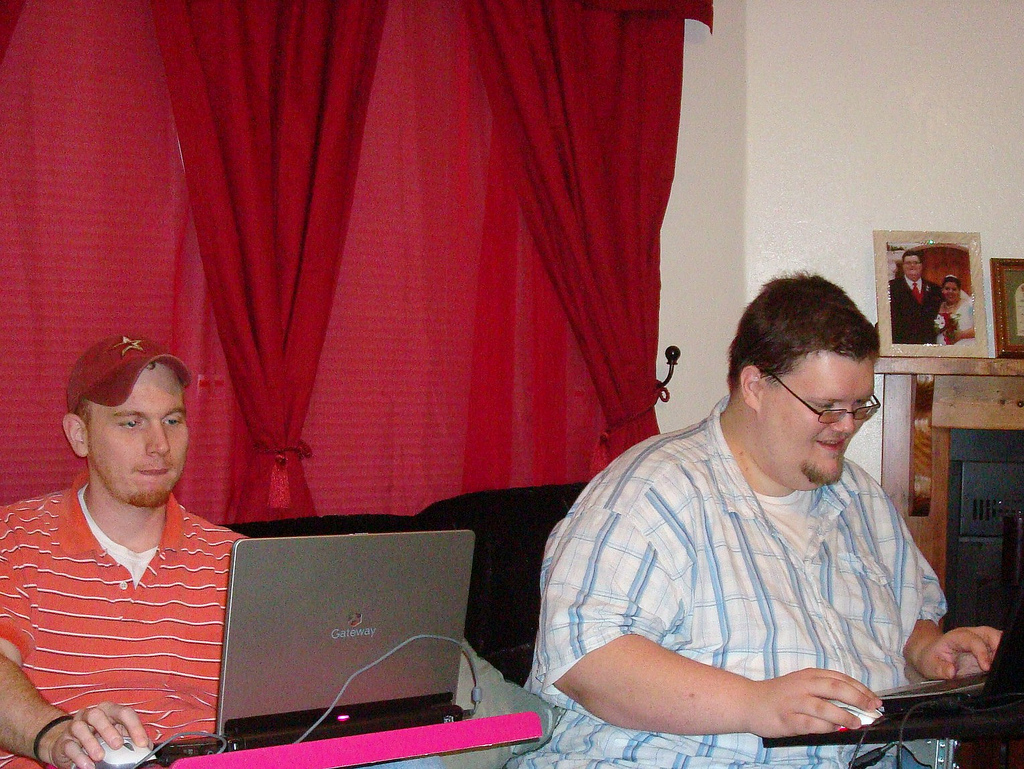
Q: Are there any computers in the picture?
A: Yes, there is a computer.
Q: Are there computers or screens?
A: Yes, there is a computer.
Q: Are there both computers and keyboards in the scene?
A: Yes, there are both a computer and a keyboard.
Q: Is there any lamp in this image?
A: No, there are no lamps.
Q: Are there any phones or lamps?
A: No, there are no lamps or phones.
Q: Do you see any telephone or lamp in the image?
A: No, there are no lamps or phones.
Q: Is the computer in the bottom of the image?
A: Yes, the computer is in the bottom of the image.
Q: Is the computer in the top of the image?
A: No, the computer is in the bottom of the image.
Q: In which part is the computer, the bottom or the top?
A: The computer is in the bottom of the image.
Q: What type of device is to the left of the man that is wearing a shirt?
A: The device is a computer.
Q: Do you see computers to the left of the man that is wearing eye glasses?
A: Yes, there is a computer to the left of the man.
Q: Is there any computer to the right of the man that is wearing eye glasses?
A: No, the computer is to the left of the man.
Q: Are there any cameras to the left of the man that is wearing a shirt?
A: No, there is a computer to the left of the man.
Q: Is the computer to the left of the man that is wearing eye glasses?
A: Yes, the computer is to the left of the man.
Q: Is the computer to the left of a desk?
A: No, the computer is to the left of the man.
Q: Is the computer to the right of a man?
A: No, the computer is to the left of a man.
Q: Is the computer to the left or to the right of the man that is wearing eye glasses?
A: The computer is to the left of the man.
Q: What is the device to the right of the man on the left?
A: The device is a computer.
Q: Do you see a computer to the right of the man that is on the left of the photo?
A: Yes, there is a computer to the right of the man.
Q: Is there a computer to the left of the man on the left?
A: No, the computer is to the right of the man.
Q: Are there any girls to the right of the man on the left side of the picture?
A: No, there is a computer to the right of the man.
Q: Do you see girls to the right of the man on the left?
A: No, there is a computer to the right of the man.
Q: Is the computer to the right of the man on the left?
A: Yes, the computer is to the right of the man.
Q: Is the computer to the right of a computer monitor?
A: No, the computer is to the right of the man.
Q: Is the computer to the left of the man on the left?
A: No, the computer is to the right of the man.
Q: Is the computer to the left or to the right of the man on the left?
A: The computer is to the right of the man.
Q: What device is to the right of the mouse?
A: The device is a computer.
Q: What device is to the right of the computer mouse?
A: The device is a computer.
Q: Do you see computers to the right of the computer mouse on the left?
A: Yes, there is a computer to the right of the computer mouse.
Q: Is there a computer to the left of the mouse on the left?
A: No, the computer is to the right of the computer mouse.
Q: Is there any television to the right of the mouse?
A: No, there is a computer to the right of the mouse.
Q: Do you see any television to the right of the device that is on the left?
A: No, there is a computer to the right of the mouse.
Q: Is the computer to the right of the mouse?
A: Yes, the computer is to the right of the mouse.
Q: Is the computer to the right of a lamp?
A: No, the computer is to the right of the mouse.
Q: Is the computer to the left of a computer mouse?
A: No, the computer is to the right of a computer mouse.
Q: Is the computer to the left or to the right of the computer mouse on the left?
A: The computer is to the right of the computer mouse.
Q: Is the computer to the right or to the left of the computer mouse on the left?
A: The computer is to the right of the computer mouse.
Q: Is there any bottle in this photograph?
A: No, there are no bottles.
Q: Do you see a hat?
A: Yes, there is a hat.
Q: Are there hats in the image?
A: Yes, there is a hat.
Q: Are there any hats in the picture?
A: Yes, there is a hat.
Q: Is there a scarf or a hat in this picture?
A: Yes, there is a hat.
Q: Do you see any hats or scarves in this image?
A: Yes, there is a hat.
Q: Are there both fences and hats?
A: No, there is a hat but no fences.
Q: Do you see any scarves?
A: No, there are no scarves.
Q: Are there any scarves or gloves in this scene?
A: No, there are no scarves or gloves.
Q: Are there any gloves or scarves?
A: No, there are no scarves or gloves.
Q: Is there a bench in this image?
A: No, there are no benches.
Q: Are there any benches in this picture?
A: No, there are no benches.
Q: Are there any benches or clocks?
A: No, there are no benches or clocks.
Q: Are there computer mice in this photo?
A: Yes, there is a computer mouse.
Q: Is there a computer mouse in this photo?
A: Yes, there is a computer mouse.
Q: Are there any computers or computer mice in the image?
A: Yes, there is a computer mouse.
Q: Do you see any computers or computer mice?
A: Yes, there is a computer mouse.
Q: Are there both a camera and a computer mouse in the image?
A: No, there is a computer mouse but no cameras.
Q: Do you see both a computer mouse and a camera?
A: No, there is a computer mouse but no cameras.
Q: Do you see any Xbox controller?
A: No, there are no Xbox controllers.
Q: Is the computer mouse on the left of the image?
A: Yes, the computer mouse is on the left of the image.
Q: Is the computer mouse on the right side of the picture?
A: No, the computer mouse is on the left of the image.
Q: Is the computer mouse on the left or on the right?
A: The computer mouse is on the left of the image.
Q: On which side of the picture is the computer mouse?
A: The computer mouse is on the left of the image.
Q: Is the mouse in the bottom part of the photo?
A: Yes, the mouse is in the bottom of the image.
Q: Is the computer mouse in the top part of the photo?
A: No, the computer mouse is in the bottom of the image.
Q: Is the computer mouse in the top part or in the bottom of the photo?
A: The computer mouse is in the bottom of the image.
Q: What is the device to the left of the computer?
A: The device is a computer mouse.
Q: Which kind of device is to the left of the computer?
A: The device is a computer mouse.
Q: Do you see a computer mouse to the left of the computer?
A: Yes, there is a computer mouse to the left of the computer.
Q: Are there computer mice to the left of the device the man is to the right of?
A: Yes, there is a computer mouse to the left of the computer.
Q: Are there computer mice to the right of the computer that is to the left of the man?
A: No, the computer mouse is to the left of the computer.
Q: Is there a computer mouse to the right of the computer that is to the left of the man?
A: No, the computer mouse is to the left of the computer.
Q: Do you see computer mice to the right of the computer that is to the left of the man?
A: No, the computer mouse is to the left of the computer.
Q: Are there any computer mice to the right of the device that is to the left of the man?
A: No, the computer mouse is to the left of the computer.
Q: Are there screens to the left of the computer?
A: No, there is a computer mouse to the left of the computer.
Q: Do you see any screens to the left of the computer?
A: No, there is a computer mouse to the left of the computer.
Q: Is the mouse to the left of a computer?
A: Yes, the mouse is to the left of a computer.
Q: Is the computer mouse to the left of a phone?
A: No, the computer mouse is to the left of a computer.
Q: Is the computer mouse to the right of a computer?
A: No, the computer mouse is to the left of a computer.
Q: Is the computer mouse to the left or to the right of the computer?
A: The computer mouse is to the left of the computer.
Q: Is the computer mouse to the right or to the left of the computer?
A: The computer mouse is to the left of the computer.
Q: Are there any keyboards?
A: Yes, there is a keyboard.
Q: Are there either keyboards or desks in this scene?
A: Yes, there is a keyboard.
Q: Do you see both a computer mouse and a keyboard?
A: Yes, there are both a keyboard and a computer mouse.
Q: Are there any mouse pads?
A: No, there are no mouse pads.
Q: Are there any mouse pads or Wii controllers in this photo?
A: No, there are no mouse pads or Wii controllers.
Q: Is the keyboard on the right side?
A: Yes, the keyboard is on the right of the image.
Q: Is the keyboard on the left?
A: No, the keyboard is on the right of the image.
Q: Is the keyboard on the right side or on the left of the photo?
A: The keyboard is on the right of the image.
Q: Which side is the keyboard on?
A: The keyboard is on the right of the image.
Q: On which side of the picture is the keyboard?
A: The keyboard is on the right of the image.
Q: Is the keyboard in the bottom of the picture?
A: Yes, the keyboard is in the bottom of the image.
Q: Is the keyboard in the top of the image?
A: No, the keyboard is in the bottom of the image.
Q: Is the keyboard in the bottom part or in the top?
A: The keyboard is in the bottom of the image.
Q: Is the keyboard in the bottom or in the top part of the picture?
A: The keyboard is in the bottom of the image.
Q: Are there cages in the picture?
A: No, there are no cages.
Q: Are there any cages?
A: No, there are no cages.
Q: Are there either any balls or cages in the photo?
A: No, there are no cages or balls.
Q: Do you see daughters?
A: No, there are no daughters.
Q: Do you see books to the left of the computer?
A: No, there is a man to the left of the computer.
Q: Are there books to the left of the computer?
A: No, there is a man to the left of the computer.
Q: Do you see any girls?
A: No, there are no girls.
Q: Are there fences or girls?
A: No, there are no girls or fences.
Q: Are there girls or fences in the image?
A: No, there are no girls or fences.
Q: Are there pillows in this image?
A: No, there are no pillows.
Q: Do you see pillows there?
A: No, there are no pillows.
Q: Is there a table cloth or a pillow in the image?
A: No, there are no pillows or tablecloths.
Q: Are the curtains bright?
A: Yes, the curtains are bright.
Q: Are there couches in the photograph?
A: Yes, there is a couch.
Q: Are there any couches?
A: Yes, there is a couch.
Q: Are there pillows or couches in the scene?
A: Yes, there is a couch.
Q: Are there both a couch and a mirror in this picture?
A: No, there is a couch but no mirrors.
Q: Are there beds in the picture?
A: No, there are no beds.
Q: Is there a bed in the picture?
A: No, there are no beds.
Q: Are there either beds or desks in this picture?
A: No, there are no beds or desks.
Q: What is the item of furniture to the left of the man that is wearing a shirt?
A: The piece of furniture is a couch.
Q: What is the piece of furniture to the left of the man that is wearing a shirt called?
A: The piece of furniture is a couch.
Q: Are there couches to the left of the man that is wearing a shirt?
A: Yes, there is a couch to the left of the man.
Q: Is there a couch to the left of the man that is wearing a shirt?
A: Yes, there is a couch to the left of the man.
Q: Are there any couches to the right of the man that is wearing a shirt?
A: No, the couch is to the left of the man.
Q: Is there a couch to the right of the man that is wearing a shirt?
A: No, the couch is to the left of the man.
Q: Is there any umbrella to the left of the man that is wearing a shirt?
A: No, there is a couch to the left of the man.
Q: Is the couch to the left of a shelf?
A: No, the couch is to the left of a man.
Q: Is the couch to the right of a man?
A: No, the couch is to the left of a man.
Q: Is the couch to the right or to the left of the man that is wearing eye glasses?
A: The couch is to the left of the man.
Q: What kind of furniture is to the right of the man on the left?
A: The piece of furniture is a couch.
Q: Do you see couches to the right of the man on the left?
A: Yes, there is a couch to the right of the man.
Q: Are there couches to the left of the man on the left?
A: No, the couch is to the right of the man.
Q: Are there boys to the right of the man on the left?
A: No, there is a couch to the right of the man.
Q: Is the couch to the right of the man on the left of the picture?
A: Yes, the couch is to the right of the man.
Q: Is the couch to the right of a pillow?
A: No, the couch is to the right of the man.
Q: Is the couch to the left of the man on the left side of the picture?
A: No, the couch is to the right of the man.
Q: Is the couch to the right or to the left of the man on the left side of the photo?
A: The couch is to the right of the man.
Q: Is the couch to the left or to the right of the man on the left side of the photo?
A: The couch is to the right of the man.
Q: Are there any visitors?
A: No, there are no visitors.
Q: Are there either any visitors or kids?
A: No, there are no visitors or kids.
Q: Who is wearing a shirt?
A: The man is wearing a shirt.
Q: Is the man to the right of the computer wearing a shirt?
A: Yes, the man is wearing a shirt.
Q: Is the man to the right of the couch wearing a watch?
A: No, the man is wearing a shirt.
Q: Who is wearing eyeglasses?
A: The man is wearing eyeglasses.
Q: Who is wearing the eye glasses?
A: The man is wearing eyeglasses.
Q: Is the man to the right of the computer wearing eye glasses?
A: Yes, the man is wearing eye glasses.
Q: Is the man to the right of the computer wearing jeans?
A: No, the man is wearing eye glasses.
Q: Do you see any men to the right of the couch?
A: Yes, there is a man to the right of the couch.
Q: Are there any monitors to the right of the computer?
A: No, there is a man to the right of the computer.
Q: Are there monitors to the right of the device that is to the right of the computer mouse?
A: No, there is a man to the right of the computer.